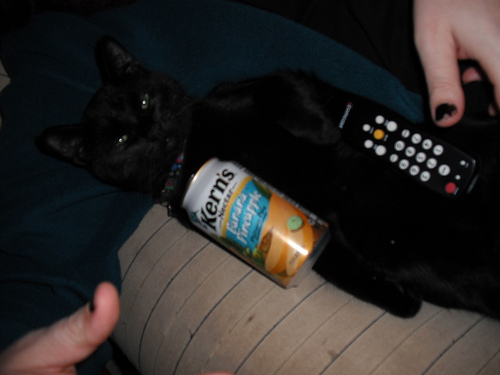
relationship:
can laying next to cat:
[177, 142, 303, 271] [57, 28, 464, 281]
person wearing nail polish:
[8, 0, 499, 375] [406, 80, 486, 128]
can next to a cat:
[182, 154, 331, 287] [39, 39, 497, 321]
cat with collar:
[39, 39, 497, 321] [153, 134, 189, 208]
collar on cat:
[151, 148, 184, 208] [37, 27, 197, 207]